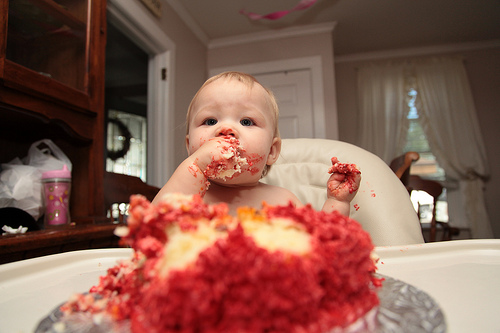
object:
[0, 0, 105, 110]
china cabinet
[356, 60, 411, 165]
curtain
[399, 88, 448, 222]
window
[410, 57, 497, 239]
white curtain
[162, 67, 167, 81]
hinge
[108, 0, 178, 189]
door frame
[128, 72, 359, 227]
baby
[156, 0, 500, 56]
ceiling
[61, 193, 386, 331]
frosting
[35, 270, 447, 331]
platter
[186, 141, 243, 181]
hand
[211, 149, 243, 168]
mouth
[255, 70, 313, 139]
door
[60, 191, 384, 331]
cake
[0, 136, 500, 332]
chair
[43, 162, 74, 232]
bottle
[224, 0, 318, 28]
streamer